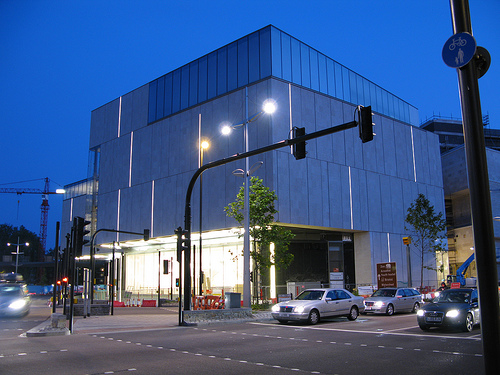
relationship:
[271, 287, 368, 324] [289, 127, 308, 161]
car near signals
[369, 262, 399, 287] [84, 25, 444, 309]
sign outside building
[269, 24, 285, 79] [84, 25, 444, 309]
window on building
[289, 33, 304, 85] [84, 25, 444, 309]
window on building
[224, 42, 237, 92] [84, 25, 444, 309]
window on building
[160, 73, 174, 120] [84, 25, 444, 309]
window on building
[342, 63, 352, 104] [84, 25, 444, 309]
window on building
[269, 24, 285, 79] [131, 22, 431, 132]
window in row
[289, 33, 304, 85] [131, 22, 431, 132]
window in row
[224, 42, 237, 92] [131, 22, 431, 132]
window in row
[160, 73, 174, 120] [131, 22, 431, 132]
window in row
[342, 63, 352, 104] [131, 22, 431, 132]
window in row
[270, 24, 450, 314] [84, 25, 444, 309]
side of building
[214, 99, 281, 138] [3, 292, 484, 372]
lamp post on street